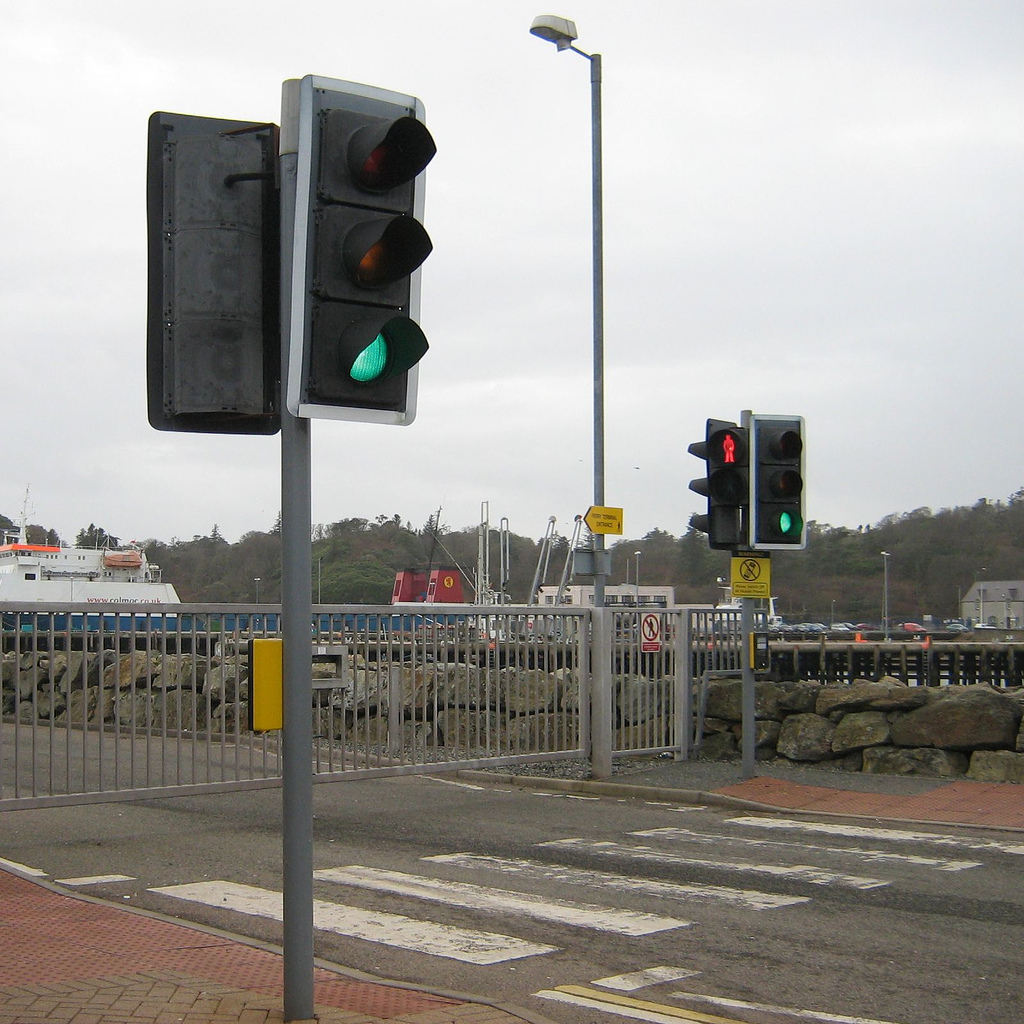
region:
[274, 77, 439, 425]
an electric traffic signal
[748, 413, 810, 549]
an electric traffic signal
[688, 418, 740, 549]
an electric traffic signal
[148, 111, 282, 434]
back of an electric traffic signal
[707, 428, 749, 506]
a do not walk signal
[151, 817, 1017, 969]
a marked pedestrian crosswalk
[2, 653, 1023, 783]
a long stone wall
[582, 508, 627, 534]
a yellow directional sign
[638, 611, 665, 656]
a no entry sign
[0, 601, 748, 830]
a long metal fence and gate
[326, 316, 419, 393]
Green light illuminated on traffic signal.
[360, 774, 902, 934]
White lines marking pavement.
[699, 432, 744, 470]
Red person illuminated on traffic signal.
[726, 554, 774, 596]
Yellow sign connected to pole.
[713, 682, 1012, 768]
Large rocks near traffic signal.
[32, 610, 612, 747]
Silver fence blocking street.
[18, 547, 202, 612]
Large ship in background.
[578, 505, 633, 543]
Yellow sign connected to pole.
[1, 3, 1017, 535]
cloud cover in sky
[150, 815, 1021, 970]
white blocks of worn paint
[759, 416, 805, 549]
glowing green traffic light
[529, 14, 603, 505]
light on top of pole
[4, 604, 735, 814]
metal rails of gate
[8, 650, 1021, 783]
surface of stone wall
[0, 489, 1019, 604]
tree tops on the horizon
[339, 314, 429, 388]
cover over glowing green light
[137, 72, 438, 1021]
traffic lights on metal pole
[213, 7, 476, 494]
the traffic light is green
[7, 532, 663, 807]
the fence is grey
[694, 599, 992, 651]
the cars are parked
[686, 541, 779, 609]
the sign is yellow and black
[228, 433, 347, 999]
the pole is grey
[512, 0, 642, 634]
the street light is tall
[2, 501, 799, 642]
boats are in the background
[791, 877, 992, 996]
the street is grey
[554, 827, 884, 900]
Lonmg white line on pavement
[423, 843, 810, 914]
Lonmg white line on pavement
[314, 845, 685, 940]
Lonmg white line on pavement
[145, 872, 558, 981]
Lonmg white line on pavement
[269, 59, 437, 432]
Traffic light on a post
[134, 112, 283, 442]
Traffic light on a post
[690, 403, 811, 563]
Traffic light on a post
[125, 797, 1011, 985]
pedestrian cross walk on a road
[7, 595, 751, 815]
metal gate across a road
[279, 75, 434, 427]
traffic light with green lit up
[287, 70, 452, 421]
green signal light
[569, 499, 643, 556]
yellow and black caution sign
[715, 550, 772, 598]
yellow and black caution sign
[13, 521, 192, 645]
blue and white docked boat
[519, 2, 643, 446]
silver light pole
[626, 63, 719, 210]
white clouds in blue sky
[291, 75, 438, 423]
glowing green traffic light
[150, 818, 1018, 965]
faded white painted blocks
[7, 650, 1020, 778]
surface of stone wall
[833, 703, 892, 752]
A stone in a wall.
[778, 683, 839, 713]
A stone in a wall.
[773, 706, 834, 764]
A stone in a wall.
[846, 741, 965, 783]
A stone in a wall.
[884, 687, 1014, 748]
A stone in a wall.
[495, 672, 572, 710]
A stone in a wall.